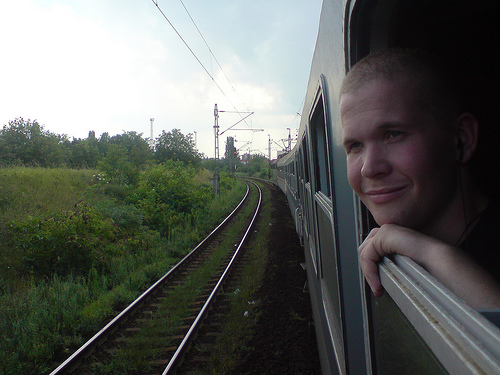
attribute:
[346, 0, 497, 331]
window — edge, train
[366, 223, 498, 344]
frame — window, dirt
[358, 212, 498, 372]
ledge — window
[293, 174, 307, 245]
train — side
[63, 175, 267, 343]
railway — line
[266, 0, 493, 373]
railway — line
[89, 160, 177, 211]
bush — green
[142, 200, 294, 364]
tracks — train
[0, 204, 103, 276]
bush — green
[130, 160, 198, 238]
bush — green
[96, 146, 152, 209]
bush — green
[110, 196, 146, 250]
bush — green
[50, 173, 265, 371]
track — train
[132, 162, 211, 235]
bush — green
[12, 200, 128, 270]
bush — green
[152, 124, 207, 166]
bush — green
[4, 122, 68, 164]
bush — green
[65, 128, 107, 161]
bush — green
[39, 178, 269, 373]
tracks — metal, train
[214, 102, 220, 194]
pole — power line